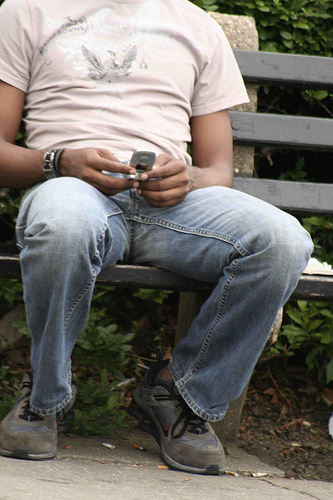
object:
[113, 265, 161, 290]
board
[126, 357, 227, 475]
shoe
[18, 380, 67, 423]
laces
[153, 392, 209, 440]
laces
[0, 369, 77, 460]
shoe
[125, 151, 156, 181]
cell phone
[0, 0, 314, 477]
man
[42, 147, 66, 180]
bracelet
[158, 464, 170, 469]
butt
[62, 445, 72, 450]
butt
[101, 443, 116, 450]
butt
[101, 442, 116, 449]
butt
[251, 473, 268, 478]
butt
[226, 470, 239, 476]
butt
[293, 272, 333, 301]
board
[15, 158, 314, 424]
jeans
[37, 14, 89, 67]
letters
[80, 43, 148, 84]
pictures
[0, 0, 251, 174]
shirt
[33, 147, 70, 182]
wristband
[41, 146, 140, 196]
hand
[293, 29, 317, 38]
leaves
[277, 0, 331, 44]
plant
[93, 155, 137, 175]
finger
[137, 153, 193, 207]
hand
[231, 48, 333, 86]
bench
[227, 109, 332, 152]
bench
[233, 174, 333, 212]
bench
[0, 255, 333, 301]
bench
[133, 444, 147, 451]
cigarette butt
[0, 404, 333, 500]
ground